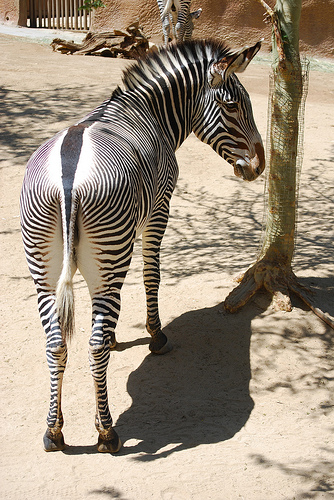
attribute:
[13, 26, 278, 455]
zebra — looking, white, black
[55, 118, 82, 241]
line — black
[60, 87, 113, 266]
stripe — black, thin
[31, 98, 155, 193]
back — zebra's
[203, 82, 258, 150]
stripes — black, white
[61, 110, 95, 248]
stripe — black, thin